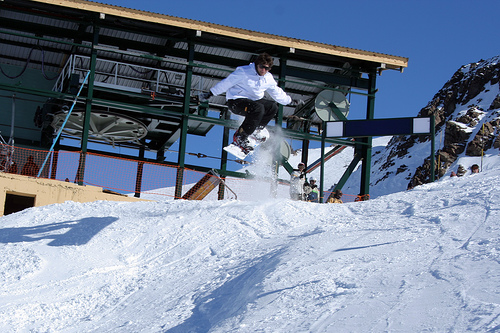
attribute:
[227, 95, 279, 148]
pants — black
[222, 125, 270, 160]
snowboard — white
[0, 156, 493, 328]
snow — white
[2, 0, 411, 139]
roof — large, metal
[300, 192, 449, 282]
snow — rocky